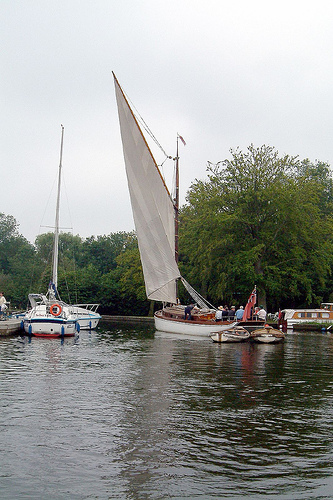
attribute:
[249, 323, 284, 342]
boat — small, white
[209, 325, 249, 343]
boat — small, white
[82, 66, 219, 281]
sailboat — white, brown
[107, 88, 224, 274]
sail — white